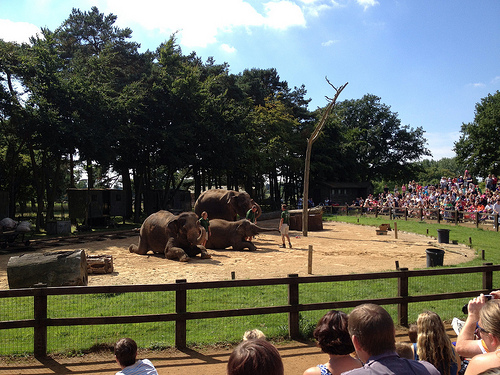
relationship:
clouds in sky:
[108, 1, 381, 54] [285, 33, 498, 63]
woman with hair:
[411, 310, 461, 373] [416, 310, 455, 373]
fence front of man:
[0, 252, 489, 368] [339, 302, 439, 375]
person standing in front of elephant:
[260, 170, 321, 255] [163, 161, 280, 248]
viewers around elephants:
[6, 133, 499, 374] [114, 179, 262, 266]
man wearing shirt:
[321, 301, 439, 373] [342, 352, 444, 372]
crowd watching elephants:
[372, 173, 497, 250] [137, 186, 258, 253]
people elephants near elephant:
[198, 211, 212, 247] [124, 207, 212, 264]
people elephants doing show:
[120, 175, 292, 264] [129, 151, 323, 269]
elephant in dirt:
[190, 184, 262, 229] [2, 215, 481, 292]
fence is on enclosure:
[0, 260, 500, 362] [2, 163, 497, 365]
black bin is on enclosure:
[431, 220, 453, 247] [2, 197, 497, 357]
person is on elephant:
[278, 203, 292, 248] [206, 217, 280, 251]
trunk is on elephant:
[259, 227, 281, 233] [203, 217, 283, 252]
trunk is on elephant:
[189, 230, 198, 257] [129, 207, 213, 261]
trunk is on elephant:
[259, 226, 285, 233] [206, 217, 280, 251]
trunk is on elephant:
[248, 197, 263, 220] [193, 187, 260, 219]